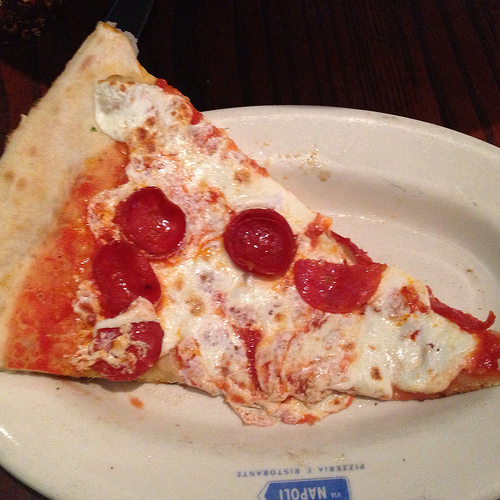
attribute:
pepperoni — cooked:
[228, 207, 295, 277]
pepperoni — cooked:
[297, 262, 384, 312]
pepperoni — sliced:
[429, 295, 496, 329]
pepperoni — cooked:
[121, 185, 187, 255]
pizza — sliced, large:
[1, 22, 500, 427]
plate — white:
[3, 378, 498, 499]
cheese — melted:
[229, 392, 353, 427]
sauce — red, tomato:
[480, 332, 499, 376]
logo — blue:
[261, 479, 349, 499]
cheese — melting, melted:
[100, 84, 479, 424]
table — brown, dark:
[139, 3, 499, 150]